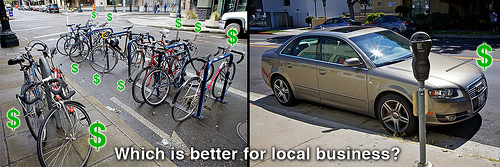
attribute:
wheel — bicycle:
[40, 81, 114, 163]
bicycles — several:
[70, 14, 237, 125]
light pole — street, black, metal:
[1, 3, 22, 50]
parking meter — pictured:
[411, 30, 433, 165]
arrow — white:
[106, 92, 201, 159]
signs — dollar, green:
[61, 53, 143, 101]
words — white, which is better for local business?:
[98, 124, 411, 161]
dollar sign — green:
[85, 116, 109, 152]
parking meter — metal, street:
[407, 27, 438, 165]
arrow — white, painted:
[107, 93, 194, 157]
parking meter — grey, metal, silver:
[406, 31, 434, 165]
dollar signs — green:
[64, 59, 126, 91]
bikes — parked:
[54, 19, 244, 124]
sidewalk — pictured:
[69, 58, 183, 135]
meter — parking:
[409, 32, 433, 165]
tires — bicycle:
[130, 68, 209, 115]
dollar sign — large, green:
[475, 37, 494, 72]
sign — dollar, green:
[473, 38, 493, 72]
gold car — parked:
[253, 12, 490, 148]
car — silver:
[268, 19, 490, 137]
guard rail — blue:
[198, 47, 238, 120]